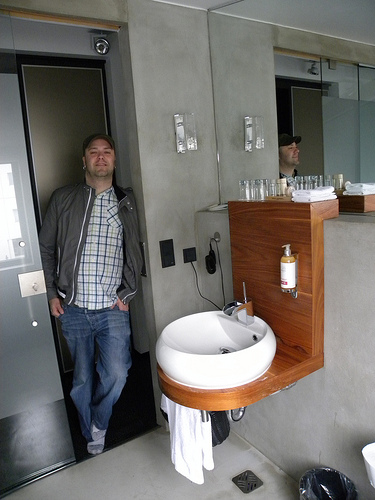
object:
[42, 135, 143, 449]
man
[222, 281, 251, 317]
faucet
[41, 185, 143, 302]
jacket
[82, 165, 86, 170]
earring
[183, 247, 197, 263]
socket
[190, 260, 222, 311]
wire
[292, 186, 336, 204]
towels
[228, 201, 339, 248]
shelf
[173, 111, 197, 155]
light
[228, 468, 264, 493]
drain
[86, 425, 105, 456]
socks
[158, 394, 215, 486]
towel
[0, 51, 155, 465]
door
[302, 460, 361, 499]
carpet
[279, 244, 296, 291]
hand soap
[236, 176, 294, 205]
detergent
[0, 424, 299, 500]
floor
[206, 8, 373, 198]
reflection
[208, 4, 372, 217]
mirror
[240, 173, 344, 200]
glasses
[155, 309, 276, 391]
sink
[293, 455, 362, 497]
plastic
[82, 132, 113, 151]
cap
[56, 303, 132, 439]
blue jeans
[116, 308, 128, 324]
pocket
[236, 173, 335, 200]
cups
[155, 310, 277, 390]
bowl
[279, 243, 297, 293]
soap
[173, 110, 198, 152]
glass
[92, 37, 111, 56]
camera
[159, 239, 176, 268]
switch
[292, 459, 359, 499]
bin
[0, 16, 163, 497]
doorway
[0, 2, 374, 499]
bathroom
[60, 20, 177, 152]
background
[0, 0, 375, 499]
wall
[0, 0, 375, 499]
house